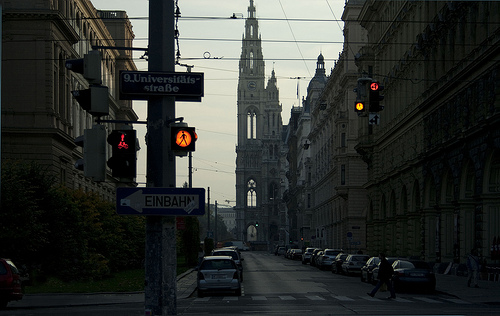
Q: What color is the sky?
A: Blue.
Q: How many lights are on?
A: Four.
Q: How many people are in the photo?
A: One.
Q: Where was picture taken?
A: Street.